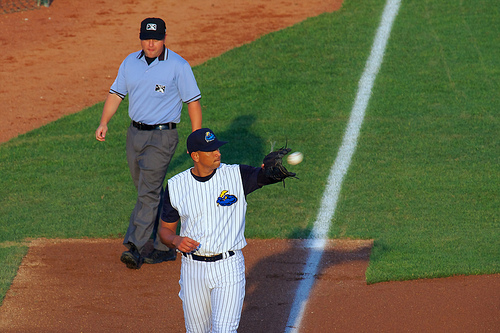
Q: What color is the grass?
A: Green.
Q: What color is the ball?
A: White.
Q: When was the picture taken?
A: Daytime.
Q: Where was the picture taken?
A: At a baseball park.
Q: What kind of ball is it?
A: A baseball.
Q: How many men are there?
A: Two.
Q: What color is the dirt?
A: Brown.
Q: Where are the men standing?
A: On the dirt.